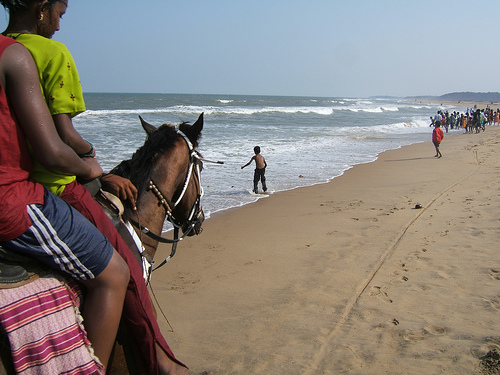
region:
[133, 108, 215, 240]
the head of a horse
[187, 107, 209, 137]
the ear of a horse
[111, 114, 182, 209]
the mane of a horse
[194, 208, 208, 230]
the nose of a horse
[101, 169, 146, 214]
the hand of a person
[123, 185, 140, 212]
the finger of a person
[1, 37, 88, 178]
the arm of a person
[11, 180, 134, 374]
the leg of a person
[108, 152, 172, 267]
the neck of a horse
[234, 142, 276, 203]
a boy in the water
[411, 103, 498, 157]
Group of people standing on beach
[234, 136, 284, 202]
Shirtless boy standing in water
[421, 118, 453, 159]
Person in red shirt starring at the ocean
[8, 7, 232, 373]
Two people riding a brown horse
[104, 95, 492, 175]
Waves coming in from off the ocean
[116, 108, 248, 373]
Brown horse wearing a white and black bridle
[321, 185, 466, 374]
One wheel tire tracks on sand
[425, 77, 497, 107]
Hills overlooking an ocean beach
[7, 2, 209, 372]
Girl wearing green shirt and red pants on horse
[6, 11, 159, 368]
Boy wearing red tank top and blue shorts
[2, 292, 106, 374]
Colorful blanket with stripes of purple, pink, orange, and green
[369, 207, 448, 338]
Line of small foot prints on tan sand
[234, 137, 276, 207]
Boy standing in frothy white water with no shirt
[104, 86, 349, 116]
Calm blue ocean water with a small white tide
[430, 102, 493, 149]
A large group of people standing on the sandy beach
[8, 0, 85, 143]
Person sitting wearing a yellowish green shirt with stars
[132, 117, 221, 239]
Head of a brown horse with a dark mane and a white harness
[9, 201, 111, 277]
Gray shorts with three white stripes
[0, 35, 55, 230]
Red shirt being worn by a person with no sleeves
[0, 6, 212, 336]
Two people riding a horse together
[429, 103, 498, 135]
people gathered on a beach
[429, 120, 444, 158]
a person walking on a beach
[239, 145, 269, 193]
a boy with his feet in the ocean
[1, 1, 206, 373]
two people riding a horse on a beach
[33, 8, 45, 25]
a woman wearing a golden earring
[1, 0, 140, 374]
a woman sitting in front of a man on a horse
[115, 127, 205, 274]
a horse's harness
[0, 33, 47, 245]
man wearing a red tank top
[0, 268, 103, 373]
a colorful blanket beneath the saddle of a horse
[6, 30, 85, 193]
woman wearing a lime green shirt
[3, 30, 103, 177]
two people on a horse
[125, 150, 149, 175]
the horse has black hair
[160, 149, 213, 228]
the horse is brown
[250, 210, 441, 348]
sand on the beach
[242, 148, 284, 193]
a person in the water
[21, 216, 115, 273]
blue and white stripped shorts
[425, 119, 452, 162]
a person walking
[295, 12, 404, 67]
the sky is clear and blue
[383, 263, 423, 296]
footprints in the sand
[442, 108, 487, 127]
people standing on the beach